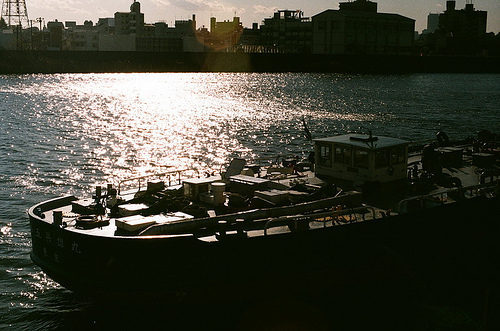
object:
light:
[8, 73, 369, 182]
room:
[310, 127, 412, 187]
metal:
[212, 180, 225, 208]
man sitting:
[421, 140, 456, 182]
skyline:
[12, 0, 491, 57]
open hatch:
[222, 158, 244, 182]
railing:
[264, 204, 376, 227]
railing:
[395, 182, 498, 209]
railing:
[119, 166, 202, 197]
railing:
[218, 152, 297, 168]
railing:
[409, 138, 432, 149]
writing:
[3, 200, 110, 292]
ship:
[23, 116, 495, 296]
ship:
[29, 130, 496, 308]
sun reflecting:
[75, 83, 257, 138]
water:
[6, 76, 485, 135]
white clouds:
[3, 1, 498, 37]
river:
[1, 72, 496, 324]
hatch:
[109, 215, 162, 234]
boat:
[29, 97, 499, 312]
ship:
[27, 132, 498, 290]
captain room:
[318, 130, 405, 185]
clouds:
[156, 1, 243, 18]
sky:
[41, 1, 326, 9]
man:
[420, 141, 445, 185]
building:
[309, 2, 418, 56]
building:
[260, 9, 311, 53]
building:
[203, 8, 246, 55]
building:
[95, 0, 198, 54]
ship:
[24, 111, 496, 328]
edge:
[153, 209, 390, 245]